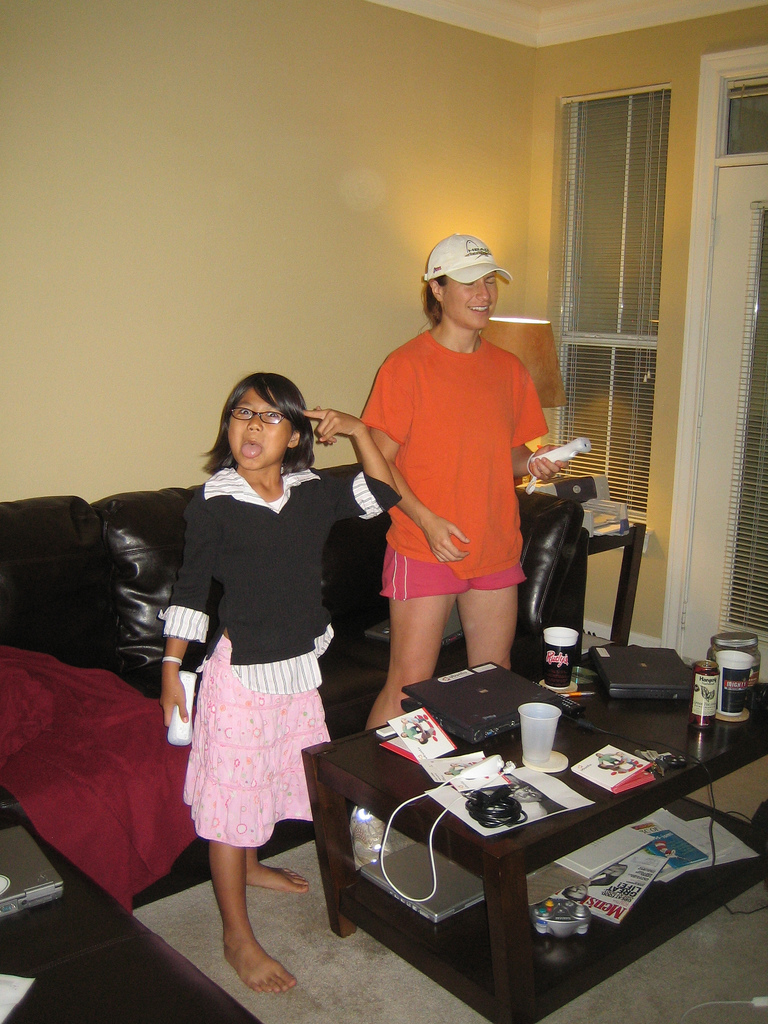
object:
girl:
[160, 372, 404, 994]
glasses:
[229, 407, 301, 433]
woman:
[360, 233, 570, 731]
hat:
[423, 233, 513, 284]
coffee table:
[301, 640, 767, 1021]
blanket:
[0, 643, 200, 917]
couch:
[0, 462, 590, 909]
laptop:
[0, 826, 64, 916]